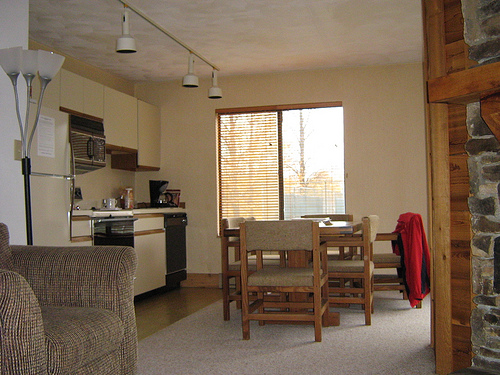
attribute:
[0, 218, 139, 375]
chair — soft, beige, grey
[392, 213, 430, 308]
jacket — red, sweater, sitting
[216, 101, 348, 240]
window — large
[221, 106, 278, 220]
blinds — brown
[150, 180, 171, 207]
pot — black, machine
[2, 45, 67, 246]
lamp — floor, standing, up, tall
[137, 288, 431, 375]
carpet — grey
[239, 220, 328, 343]
chair — beige, cushioned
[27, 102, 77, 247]
fridge — white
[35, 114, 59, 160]
paper — white, attached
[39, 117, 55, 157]
lettering — black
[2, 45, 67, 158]
light — up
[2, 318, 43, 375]
pattern — stiched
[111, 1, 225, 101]
style — track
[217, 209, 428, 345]
set — wooden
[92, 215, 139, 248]
oven — smooth, black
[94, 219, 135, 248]
door — black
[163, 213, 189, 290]
dishwasher — black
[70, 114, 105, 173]
steel — stainless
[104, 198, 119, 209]
cup — white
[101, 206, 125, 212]
plate — white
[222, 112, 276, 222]
tree — barren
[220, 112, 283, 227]
window — rectangular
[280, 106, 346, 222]
window — rectangular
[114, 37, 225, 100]
lights — white